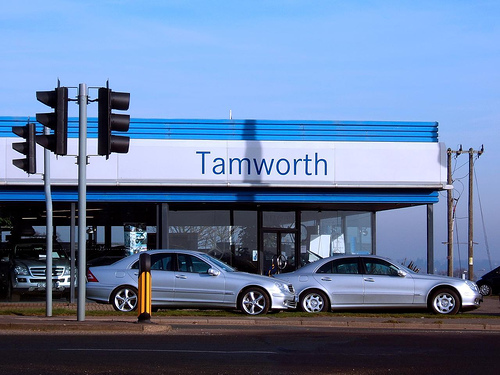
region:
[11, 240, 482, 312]
three silver Mercedes-Benz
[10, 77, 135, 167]
three black street lights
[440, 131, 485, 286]
two brown powerlines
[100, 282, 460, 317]
four tires with wheels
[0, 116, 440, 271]
blue and white car dealership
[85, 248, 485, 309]
two silver four door sedans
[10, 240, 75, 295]
silver Mercedes Benz SUV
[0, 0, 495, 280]
blue sky with no clouds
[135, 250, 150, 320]
black and yellow reflecter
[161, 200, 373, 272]
windows with black framing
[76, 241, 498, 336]
two parked silver cars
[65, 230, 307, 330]
a single parked silver car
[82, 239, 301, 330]
a parked car behind a post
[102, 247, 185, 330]
a yellow and black post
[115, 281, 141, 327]
the rear wheel of a car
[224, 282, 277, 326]
the front wheel of a car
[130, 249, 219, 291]
the windows of a car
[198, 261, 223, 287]
the side mirror of a car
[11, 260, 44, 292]
the headlight of a car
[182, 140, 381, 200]
blue letters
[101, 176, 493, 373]
cars are very visible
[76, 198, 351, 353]
cars are very visible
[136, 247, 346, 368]
cars are very visible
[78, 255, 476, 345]
two silver cars parked in front of a building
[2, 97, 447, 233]
a blue and white building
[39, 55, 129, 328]
a metal pole with two traffic lights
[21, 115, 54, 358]
a metal pole with a traffic light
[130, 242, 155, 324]
a yellow and black sign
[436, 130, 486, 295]
two wooden electrical poles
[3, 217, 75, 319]
a grey pick up truck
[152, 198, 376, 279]
a large glass window and door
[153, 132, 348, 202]
blue letters on a building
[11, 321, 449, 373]
white lines painted on a roadway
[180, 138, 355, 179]
The blue letters spell out Tamworth.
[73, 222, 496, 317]
Two cars are next to each other.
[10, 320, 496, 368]
The street has a shadow on it.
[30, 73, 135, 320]
A pole with traffic lights on it.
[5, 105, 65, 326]
Another pole with traffic lights attached.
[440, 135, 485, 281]
Two power poles.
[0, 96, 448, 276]
The building is blue and white.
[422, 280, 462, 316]
The front tire of a car.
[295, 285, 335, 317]
The back tire of a car.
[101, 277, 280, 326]
Two tires on a car.